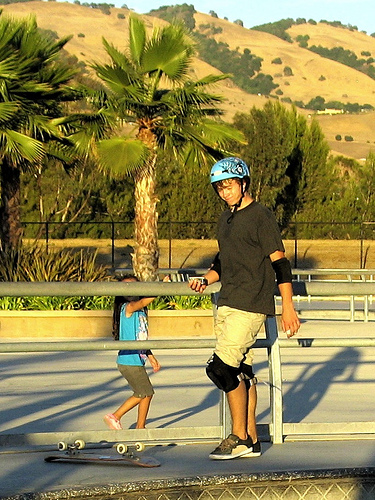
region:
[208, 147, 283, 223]
a boy wearing a helmet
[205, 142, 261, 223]
a boy wearing a blue helmet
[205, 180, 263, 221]
the head of a boy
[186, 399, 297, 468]
a boy wearing shoes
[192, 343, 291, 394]
a boy wearing knee pads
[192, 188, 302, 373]
a boy wearing a shirt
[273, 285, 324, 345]
the hand of a boy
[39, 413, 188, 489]
a skateboard on the ground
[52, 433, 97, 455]
wheels on a skateboard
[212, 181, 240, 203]
the eyes of a boy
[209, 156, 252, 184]
man wearing light blue helmet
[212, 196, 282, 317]
man wearing gray shirt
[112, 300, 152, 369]
little girl wearing blue tshirt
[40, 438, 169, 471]
skateboard flipped over on ground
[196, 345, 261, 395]
man wearing knee pads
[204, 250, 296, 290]
man wearing elbow pads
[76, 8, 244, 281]
palm tree in background is green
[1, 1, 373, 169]
hills are dry and brown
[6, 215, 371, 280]
railing back is black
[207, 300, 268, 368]
man wearing khaki shorts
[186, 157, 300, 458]
Boy looking at camera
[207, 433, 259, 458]
Shoes are multi colored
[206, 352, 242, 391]
Knee pad is black and white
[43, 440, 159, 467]
Skateboard is upside down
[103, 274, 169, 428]
A girl is walking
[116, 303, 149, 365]
The shirt is blue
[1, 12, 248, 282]
A couple of palm trees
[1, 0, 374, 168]
Hills in the background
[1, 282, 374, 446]
The rail is made of metal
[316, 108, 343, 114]
A building on the hill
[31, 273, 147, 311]
thick silver railing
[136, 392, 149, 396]
brown button on edge of green pants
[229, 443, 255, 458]
yellow color on sneakers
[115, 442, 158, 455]
yellow wheels on skate board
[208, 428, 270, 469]
yellow and brown felt sneakers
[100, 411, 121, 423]
pink and white sneakers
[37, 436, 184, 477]
over turned skate board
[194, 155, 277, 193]
blue and black helmet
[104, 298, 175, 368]
short sleeve blue shirt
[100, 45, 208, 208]
tall palm trees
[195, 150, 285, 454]
this is a man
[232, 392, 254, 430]
the man is light skinned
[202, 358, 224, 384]
this is a knee pad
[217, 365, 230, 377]
the pad is black in color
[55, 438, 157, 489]
this is a skateboard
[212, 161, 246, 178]
this is the helmet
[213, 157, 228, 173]
the helmet is blue in color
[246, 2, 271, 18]
this is the sky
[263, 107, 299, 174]
this is a tree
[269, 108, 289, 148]
the leaves are green in color